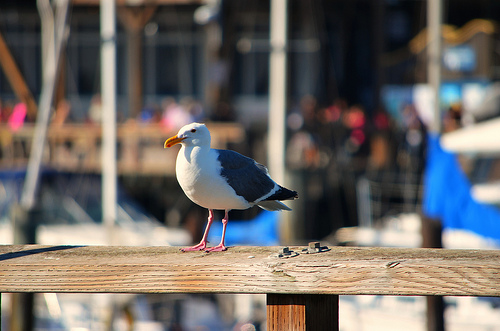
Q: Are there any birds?
A: Yes, there is a bird.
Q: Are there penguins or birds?
A: Yes, there is a bird.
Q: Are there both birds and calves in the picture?
A: No, there is a bird but no calves.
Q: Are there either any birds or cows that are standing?
A: Yes, the bird is standing.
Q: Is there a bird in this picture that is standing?
A: Yes, there is a bird that is standing.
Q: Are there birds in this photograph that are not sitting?
A: Yes, there is a bird that is standing.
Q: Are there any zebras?
A: No, there are no zebras.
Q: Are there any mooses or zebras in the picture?
A: No, there are no zebras or mooses.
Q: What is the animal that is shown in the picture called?
A: The animal is a bird.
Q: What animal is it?
A: The animal is a bird.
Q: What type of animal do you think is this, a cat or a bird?
A: This is a bird.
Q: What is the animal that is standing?
A: The animal is a bird.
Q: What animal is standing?
A: The animal is a bird.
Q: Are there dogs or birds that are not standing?
A: No, there is a bird but it is standing.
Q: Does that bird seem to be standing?
A: Yes, the bird is standing.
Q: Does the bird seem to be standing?
A: Yes, the bird is standing.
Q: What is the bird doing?
A: The bird is standing.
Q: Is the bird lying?
A: No, the bird is standing.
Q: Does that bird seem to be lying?
A: No, the bird is standing.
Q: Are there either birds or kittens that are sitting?
A: No, there is a bird but it is standing.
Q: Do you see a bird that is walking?
A: No, there is a bird but it is standing.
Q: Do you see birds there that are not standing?
A: No, there is a bird but it is standing.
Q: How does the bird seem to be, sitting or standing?
A: The bird is standing.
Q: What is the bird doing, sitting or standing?
A: The bird is standing.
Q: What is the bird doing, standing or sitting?
A: The bird is standing.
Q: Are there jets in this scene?
A: No, there are no jets.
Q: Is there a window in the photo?
A: Yes, there is a window.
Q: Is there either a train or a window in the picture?
A: Yes, there is a window.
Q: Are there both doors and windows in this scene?
A: No, there is a window but no doors.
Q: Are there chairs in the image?
A: No, there are no chairs.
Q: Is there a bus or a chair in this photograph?
A: No, there are no chairs or buses.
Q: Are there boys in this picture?
A: No, there are no boys.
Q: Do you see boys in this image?
A: No, there are no boys.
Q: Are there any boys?
A: No, there are no boys.